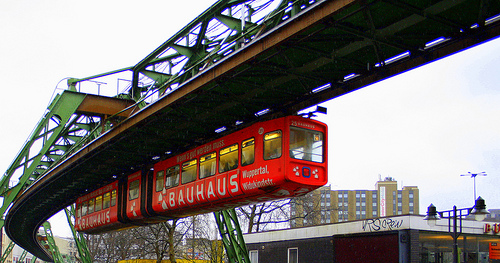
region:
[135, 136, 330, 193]
red train uner bridge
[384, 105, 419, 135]
white clouds in blue sky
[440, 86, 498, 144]
white clouds in blue sky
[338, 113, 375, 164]
white clouds in blue sky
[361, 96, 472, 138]
white clouds in blue sky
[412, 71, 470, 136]
white clouds in blue sky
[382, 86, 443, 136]
white clouds in blue sky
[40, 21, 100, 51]
white clouds in blue sky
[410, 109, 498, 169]
white clouds in blue sky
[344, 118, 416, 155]
white clouds in blue sky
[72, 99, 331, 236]
Red light rail car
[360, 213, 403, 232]
Graffiti on building facade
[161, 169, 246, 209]
Bauhaus on side of rail car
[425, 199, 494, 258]
Black power poles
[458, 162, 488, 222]
Metal antenna sticking up from roof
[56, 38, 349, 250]
Railcar attached to bottom of tracks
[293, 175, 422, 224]
Tan building in background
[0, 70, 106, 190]
Green scaffolding to rail tracks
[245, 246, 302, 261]
Two windows to building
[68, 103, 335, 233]
Two red rail cars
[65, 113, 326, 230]
a hanging red train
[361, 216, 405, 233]
spray paint on the building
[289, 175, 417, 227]
tall building in the background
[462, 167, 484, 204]
a street light pole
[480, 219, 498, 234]
red business sign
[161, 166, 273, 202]
white writing on the train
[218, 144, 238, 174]
passenger in the window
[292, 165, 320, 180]
lights on the front of the train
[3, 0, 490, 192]
the skies are overcast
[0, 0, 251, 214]
green metal framing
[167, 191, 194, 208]
white letters on train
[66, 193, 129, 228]
red train car on track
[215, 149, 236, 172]
window on train car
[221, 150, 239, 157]
light in window on train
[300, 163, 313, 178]
blue square on train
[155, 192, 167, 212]
white symbol on red train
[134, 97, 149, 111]
silver rails on track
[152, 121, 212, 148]
track above red train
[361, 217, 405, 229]
black graffiti on building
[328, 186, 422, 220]
tall buildings in sky line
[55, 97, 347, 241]
train traveling on a bridge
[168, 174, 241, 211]
white lettering on red background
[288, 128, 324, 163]
front window on train car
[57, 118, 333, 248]
two red train cars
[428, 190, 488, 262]
pole with two street lamps on it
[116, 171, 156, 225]
doors on the red train cars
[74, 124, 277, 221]
windows on side of train cars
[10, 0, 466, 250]
sky tracks train is traveling on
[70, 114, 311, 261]
trees behind the train cars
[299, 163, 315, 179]
blue square on front of train